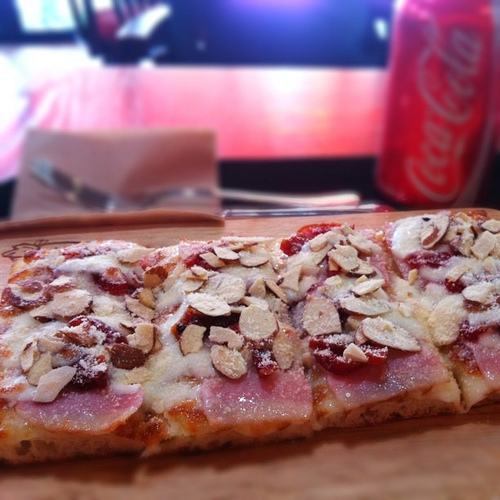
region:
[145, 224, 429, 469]
the pizza is sliced with square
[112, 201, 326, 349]
the pizza is sliced with square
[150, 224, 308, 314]
the pizza is sliced with square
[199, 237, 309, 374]
the pizza is sliced with square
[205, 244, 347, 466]
the pizza is sliced with square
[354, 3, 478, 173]
red can of coke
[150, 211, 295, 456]
piece of bread with nuts on it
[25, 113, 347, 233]
fork on a napkin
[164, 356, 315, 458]
toasted bread with cranberries on it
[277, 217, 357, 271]
cranberries and nuts on bread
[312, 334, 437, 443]
piece of meat on toasted bread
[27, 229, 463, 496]
bread on a wooden tay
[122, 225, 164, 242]
wood tray holding food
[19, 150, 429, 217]
napkin under a fork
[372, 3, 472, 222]
can of soda on tray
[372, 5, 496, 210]
red and white soda can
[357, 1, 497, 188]
soda can says coca cola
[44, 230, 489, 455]
pizza bread with toppings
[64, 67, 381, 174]
red table in background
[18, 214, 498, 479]
pizza bread on brown counter top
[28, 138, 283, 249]
white napkin in photograph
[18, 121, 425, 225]
silver fork on white napkin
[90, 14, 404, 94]
black chair by red table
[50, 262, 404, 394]
several toppings on pizza bread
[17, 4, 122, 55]
door to building partially visible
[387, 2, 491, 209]
blurry can of coca-cola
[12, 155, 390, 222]
blurrus silverware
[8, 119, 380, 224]
silverware sits on napkin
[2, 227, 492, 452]
dish is made with cheese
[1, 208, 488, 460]
dish is made with meat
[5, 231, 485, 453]
dish is made with almonds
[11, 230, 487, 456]
dish is made with bread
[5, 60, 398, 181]
surface of table is red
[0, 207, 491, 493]
food sits on brown wooden surface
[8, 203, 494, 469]
four servings of the same dish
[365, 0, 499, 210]
red coca cola can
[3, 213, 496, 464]
two rows of pizza squares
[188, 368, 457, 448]
square ham slices on pizza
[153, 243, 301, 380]
almond-looking condiment on pizza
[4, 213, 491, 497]
pizza on top of wooden table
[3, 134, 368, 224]
silver fork on top of napkin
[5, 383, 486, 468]
pizza bread crusts cut up into squares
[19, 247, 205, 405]
powdered cheese on top of pizza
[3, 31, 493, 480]
meal of pizza and soda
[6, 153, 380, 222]
metal utensils on a table